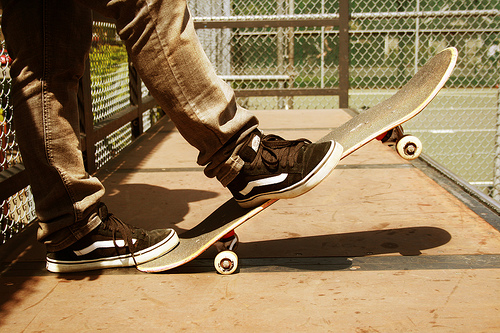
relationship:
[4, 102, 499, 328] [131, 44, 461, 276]
ramp for skateboard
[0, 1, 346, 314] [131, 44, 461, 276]
man on skateboard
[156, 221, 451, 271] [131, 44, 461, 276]
shadow by skateboard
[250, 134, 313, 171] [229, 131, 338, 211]
laces on sneaker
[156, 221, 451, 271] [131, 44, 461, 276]
shadow of skateboard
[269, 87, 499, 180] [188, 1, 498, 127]
court on side of fence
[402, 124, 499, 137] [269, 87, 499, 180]
line on court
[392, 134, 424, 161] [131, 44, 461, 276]
wheel on skateboard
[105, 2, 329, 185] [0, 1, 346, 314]
leg of man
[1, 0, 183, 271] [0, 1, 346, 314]
leg of man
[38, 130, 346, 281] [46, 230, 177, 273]
shoes have soles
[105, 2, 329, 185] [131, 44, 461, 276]
leg pressing skateboard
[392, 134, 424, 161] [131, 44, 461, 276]
wheel in front of skateboard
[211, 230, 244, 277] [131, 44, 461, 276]
wheels on skateboard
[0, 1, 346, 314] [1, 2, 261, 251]
man wears jeans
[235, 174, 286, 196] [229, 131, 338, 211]
stripe on sneaker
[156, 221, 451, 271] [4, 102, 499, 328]
shadow on ramp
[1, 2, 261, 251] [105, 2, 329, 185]
jeans on leg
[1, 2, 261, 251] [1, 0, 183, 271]
jeans on leg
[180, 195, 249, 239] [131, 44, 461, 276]
shadow on skateboard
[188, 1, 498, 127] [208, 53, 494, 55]
fence in background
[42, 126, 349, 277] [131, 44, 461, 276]
feet holding skateboard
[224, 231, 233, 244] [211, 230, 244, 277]
details on wheels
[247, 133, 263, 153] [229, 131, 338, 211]
tag on sneaker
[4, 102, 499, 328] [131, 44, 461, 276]
ramp under skateboard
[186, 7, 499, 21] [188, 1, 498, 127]
post along fence